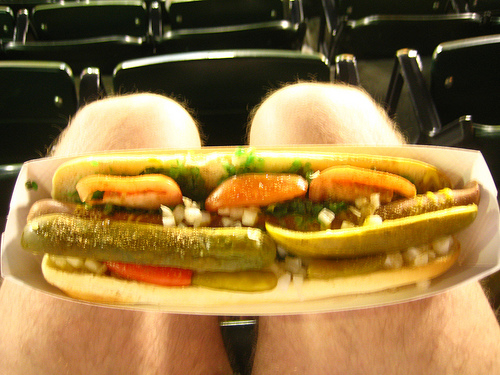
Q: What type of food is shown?
A: Hot dog.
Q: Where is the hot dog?
A: Paper container.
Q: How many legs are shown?
A: 2.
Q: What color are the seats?
A: Black.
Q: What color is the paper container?
A: White.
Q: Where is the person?
A: In a stadium.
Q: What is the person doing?
A: Eating a hot dog.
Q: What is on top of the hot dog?
A: Pickles.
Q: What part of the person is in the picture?
A: Legs.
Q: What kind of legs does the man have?
A: Hairy.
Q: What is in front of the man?
A: Seats.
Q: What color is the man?
A: White.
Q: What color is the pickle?
A: Green.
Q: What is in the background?
A: Stadium chairs.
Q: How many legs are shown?
A: Two.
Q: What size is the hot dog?
A: Footlong.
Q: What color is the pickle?
A: Green.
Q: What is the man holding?
A: A sausage.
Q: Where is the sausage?
A: On a mans lap.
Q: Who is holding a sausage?
A: A man.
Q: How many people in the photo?
A: One.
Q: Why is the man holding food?
A: To eat.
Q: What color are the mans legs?
A: White.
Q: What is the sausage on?
A: A bun.